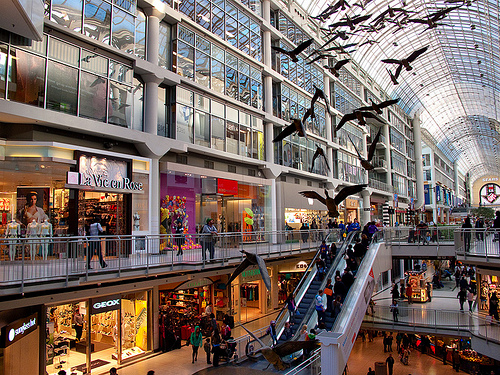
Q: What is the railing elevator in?
A: A mall.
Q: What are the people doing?
A: Shopping.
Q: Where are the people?
A: In the mall.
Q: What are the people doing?
A: Walking.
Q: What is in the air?
A: Birds.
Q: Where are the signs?
A: Above the doors.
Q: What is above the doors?
A: Signs.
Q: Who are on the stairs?
A: Customers.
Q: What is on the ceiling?
A: Windows.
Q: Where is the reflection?
A: In the mirrors.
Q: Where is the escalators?
A: In the mall.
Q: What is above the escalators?
A: Birds.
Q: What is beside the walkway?
A: A railing.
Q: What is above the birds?
A: The roof..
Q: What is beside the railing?
A: A person.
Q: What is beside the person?
A: A store.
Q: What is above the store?
A: Mirrors.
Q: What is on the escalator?
A: Stairs.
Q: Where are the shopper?
A: Escalator.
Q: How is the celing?
A: Glass.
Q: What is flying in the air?
A: Birds.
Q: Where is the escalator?
A: Middle of mall.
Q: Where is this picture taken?
A: Mall.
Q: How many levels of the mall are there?
A: Three.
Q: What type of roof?
A: Glass.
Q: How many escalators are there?
A: Two.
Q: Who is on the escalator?
A: People.